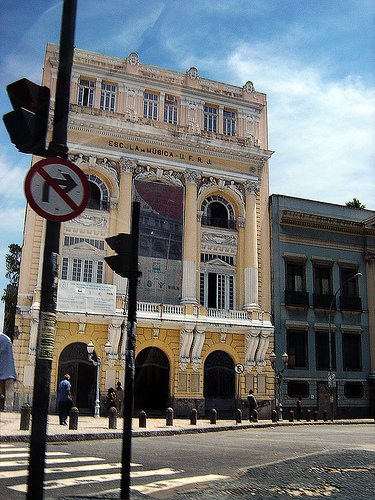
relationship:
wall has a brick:
[2, 40, 276, 409] [163, 332, 179, 351]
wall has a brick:
[2, 40, 276, 409] [93, 327, 106, 350]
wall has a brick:
[2, 40, 276, 409] [31, 240, 41, 250]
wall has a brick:
[2, 40, 276, 409] [15, 342, 25, 355]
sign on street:
[26, 155, 93, 225] [2, 410, 370, 494]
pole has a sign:
[17, 0, 82, 494] [26, 155, 93, 225]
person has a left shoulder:
[2, 325, 14, 412] [4, 329, 16, 390]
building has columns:
[2, 40, 276, 409] [102, 156, 262, 323]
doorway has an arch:
[133, 344, 173, 417] [133, 345, 173, 412]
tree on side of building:
[1, 241, 21, 347] [2, 40, 276, 409]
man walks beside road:
[56, 371, 73, 425] [2, 410, 370, 494]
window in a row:
[76, 76, 121, 116] [74, 74, 122, 115]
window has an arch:
[196, 181, 236, 317] [196, 184, 239, 235]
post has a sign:
[17, 0, 82, 494] [26, 155, 93, 225]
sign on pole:
[26, 155, 93, 225] [17, 0, 82, 494]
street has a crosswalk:
[2, 410, 370, 494] [2, 437, 230, 499]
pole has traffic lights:
[17, 0, 82, 494] [2, 74, 49, 155]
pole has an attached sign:
[17, 0, 82, 494] [26, 155, 93, 225]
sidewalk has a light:
[5, 402, 370, 438] [84, 338, 113, 419]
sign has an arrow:
[26, 155, 93, 225] [37, 172, 76, 204]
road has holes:
[2, 410, 370, 494] [268, 457, 361, 494]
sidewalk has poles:
[5, 402, 370, 438] [320, 264, 360, 420]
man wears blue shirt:
[56, 371, 73, 425] [55, 378, 73, 402]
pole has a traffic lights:
[17, 0, 82, 494] [2, 74, 49, 155]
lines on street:
[0, 441, 231, 499] [2, 410, 370, 494]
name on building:
[107, 139, 212, 165] [2, 40, 276, 409]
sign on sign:
[36, 312, 58, 361] [34, 312, 58, 364]